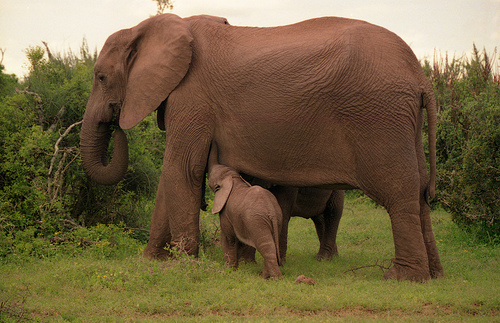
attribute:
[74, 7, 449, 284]
elephants — large 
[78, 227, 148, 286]
field — grassy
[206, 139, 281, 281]
elephant — a baby, small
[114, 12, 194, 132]
ear — large 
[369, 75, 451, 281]
leg — hind leg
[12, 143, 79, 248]
trees — short 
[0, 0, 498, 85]
sky — dusky , yellow , gray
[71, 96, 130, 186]
trunk — curled 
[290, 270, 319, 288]
brown rock — brown 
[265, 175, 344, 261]
elephant — small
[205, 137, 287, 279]
elephant — baby , mama 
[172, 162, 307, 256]
baby elephant — small 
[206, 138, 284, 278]
baby elephant — baby 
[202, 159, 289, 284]
baby elephant — a baby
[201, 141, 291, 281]
elephant — small 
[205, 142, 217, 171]
trunk — up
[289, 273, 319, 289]
poop — in a pile, elephant poop